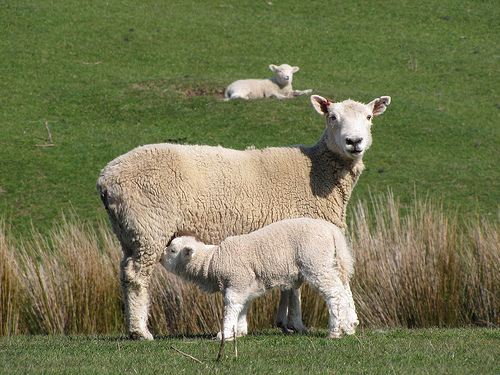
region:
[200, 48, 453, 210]
the sheep is lying in the grass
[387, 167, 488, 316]
the grass is overgrown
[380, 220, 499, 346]
the grass is dead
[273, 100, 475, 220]
the lamp has a white face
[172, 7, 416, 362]
three lambs are in the photo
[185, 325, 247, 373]
sticks are on the ground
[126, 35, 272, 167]
dirt is on the ground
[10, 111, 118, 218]
sticks are in the grass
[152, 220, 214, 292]
nursing baby sheep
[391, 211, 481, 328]
tall yellow weed like grass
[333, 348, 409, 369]
short green grass on ground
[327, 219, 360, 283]
tail on back of sheep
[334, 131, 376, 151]
nose on face of sheep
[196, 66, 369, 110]
sheep lying down in distance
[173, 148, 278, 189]
furry back of sheep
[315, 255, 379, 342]
rear legs on baby sheep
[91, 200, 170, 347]
rear legs on mother sheep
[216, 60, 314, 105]
a white colored sheep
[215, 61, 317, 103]
a white sheep laying in the grass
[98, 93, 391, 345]
an adult white sheep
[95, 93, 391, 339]
a sheep looking at the camera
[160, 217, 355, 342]
a baby white sheep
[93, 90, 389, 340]
a mamma sheep and a nursing baby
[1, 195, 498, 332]
tall brown grass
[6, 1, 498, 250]
hillside covered with green grass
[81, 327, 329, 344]
shadows on the ground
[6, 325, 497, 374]
flat land covered with grass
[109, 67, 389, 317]
sheep in a field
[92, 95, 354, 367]
sheep in a grass field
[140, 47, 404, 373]
sheep standing in a field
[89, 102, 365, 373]
sheep standing on the field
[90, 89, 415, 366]
sheep walking in a field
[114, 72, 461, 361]
sheep walking on the grass field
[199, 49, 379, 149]
sheep laying on a field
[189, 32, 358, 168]
sheep laying on the grass field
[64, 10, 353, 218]
a green grass field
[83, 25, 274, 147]
a field of green grass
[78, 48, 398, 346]
THE SHEEP ARE WHITE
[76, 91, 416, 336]
THE SHEEP ARE WOOLY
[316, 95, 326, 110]
THE EWE HAS A TAG ON HER EAR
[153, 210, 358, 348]
THE LAMB IS FUZZY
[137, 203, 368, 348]
THE LAMB IS FLUFFY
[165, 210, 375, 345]
THE LAMB IS SMALL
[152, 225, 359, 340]
THE LAMB IS WOOLY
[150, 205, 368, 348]
THE LITTLE LAMB IS NURSING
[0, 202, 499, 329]
THIS GRASS IS TALL AND BROWN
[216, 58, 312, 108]
THIS LAMB IS LYING IN THE LUSH, GREEN GRASS